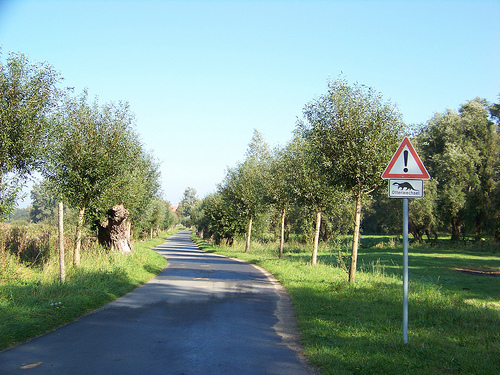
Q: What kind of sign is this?
A: Warning.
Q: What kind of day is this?
A: Sunny.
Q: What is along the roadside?
A: Trees.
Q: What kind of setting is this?
A: Country.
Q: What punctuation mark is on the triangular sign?
A: Exclamation point.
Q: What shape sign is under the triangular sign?
A: Rectangle.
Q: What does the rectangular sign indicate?
A: Animal crossing.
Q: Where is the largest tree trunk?
A: Left side of road.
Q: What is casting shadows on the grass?
A: Trees.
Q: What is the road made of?
A: Gray concrete.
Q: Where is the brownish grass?
A: Left of road.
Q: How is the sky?
A: Clear, blue, and sunny.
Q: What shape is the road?
A: Long and slightly curvy.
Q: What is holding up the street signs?
A: Metal pole.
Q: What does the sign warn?
A: Animal crossing.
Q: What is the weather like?
A: Sunny.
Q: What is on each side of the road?
A: Trees.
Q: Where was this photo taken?
A: On a country road.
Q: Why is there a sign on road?
A: To warn travelers.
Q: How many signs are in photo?
A: One.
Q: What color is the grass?
A: Green.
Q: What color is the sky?
A: Blue.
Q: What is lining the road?
A: Trees.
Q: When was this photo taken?
A: In the daytime.